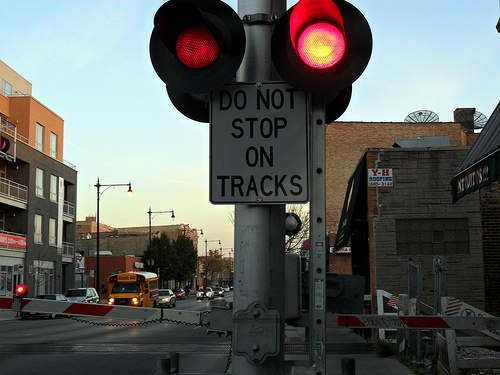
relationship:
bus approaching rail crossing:
[108, 267, 160, 309] [1, 0, 499, 370]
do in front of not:
[215, 87, 244, 112] [258, 90, 293, 110]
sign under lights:
[198, 80, 325, 205] [148, 0, 384, 125]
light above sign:
[268, 6, 351, 73] [200, 79, 322, 246]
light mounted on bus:
[107, 294, 115, 304] [108, 270, 158, 312]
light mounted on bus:
[130, 297, 140, 304] [108, 270, 158, 312]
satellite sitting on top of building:
[404, 109, 439, 122] [326, 122, 480, 274]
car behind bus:
[157, 285, 177, 305] [106, 263, 158, 304]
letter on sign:
[228, 114, 247, 141] [210, 81, 312, 205]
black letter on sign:
[257, 145, 275, 168] [210, 81, 312, 205]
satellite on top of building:
[406, 105, 441, 124] [325, 120, 469, 219]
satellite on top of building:
[455, 104, 490, 130] [325, 120, 469, 219]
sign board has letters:
[202, 71, 320, 211] [215, 93, 302, 200]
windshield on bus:
[108, 278, 143, 296] [105, 270, 159, 309]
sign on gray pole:
[210, 81, 312, 205] [237, 207, 268, 307]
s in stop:
[227, 117, 247, 144] [229, 114, 289, 141]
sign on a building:
[367, 166, 393, 186] [330, 135, 492, 335]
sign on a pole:
[210, 81, 312, 205] [234, 1, 283, 371]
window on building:
[32, 123, 47, 155] [0, 60, 78, 321]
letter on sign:
[214, 87, 235, 114] [210, 81, 312, 205]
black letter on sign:
[256, 86, 273, 111] [210, 81, 312, 205]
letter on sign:
[288, 84, 300, 110] [196, 69, 316, 210]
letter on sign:
[273, 115, 286, 139] [210, 81, 312, 205]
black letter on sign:
[230, 173, 246, 198] [210, 81, 312, 205]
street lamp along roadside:
[90, 175, 137, 290] [2, 269, 241, 372]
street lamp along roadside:
[140, 209, 182, 265] [2, 269, 241, 372]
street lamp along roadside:
[177, 227, 209, 239] [2, 269, 241, 372]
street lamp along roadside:
[201, 235, 223, 274] [2, 269, 241, 372]